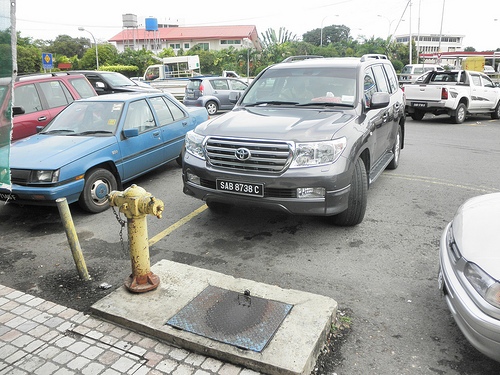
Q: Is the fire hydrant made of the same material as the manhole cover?
A: Yes, both the fire hydrant and the manhole cover are made of metal.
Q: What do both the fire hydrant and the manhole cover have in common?
A: The material, both the fire hydrant and the manhole cover are metallic.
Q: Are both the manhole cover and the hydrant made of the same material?
A: Yes, both the manhole cover and the hydrant are made of metal.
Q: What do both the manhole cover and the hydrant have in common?
A: The material, both the manhole cover and the hydrant are metallic.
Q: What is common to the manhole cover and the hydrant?
A: The material, both the manhole cover and the hydrant are metallic.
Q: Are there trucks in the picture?
A: Yes, there is a truck.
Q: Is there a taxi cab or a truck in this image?
A: Yes, there is a truck.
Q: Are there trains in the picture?
A: No, there are no trains.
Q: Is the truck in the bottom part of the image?
A: No, the truck is in the top of the image.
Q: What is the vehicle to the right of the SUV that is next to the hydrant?
A: The vehicle is a truck.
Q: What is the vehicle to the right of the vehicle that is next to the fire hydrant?
A: The vehicle is a truck.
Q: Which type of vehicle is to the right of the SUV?
A: The vehicle is a truck.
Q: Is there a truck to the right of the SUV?
A: Yes, there is a truck to the right of the SUV.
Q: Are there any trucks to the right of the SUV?
A: Yes, there is a truck to the right of the SUV.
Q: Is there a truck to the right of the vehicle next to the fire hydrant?
A: Yes, there is a truck to the right of the SUV.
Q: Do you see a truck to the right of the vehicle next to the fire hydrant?
A: Yes, there is a truck to the right of the SUV.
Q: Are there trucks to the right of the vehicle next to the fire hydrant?
A: Yes, there is a truck to the right of the SUV.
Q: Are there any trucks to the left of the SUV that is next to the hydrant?
A: No, the truck is to the right of the SUV.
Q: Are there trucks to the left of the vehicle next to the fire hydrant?
A: No, the truck is to the right of the SUV.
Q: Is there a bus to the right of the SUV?
A: No, there is a truck to the right of the SUV.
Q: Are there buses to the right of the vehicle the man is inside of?
A: No, there is a truck to the right of the SUV.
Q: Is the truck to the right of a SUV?
A: Yes, the truck is to the right of a SUV.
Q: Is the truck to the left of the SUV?
A: No, the truck is to the right of the SUV.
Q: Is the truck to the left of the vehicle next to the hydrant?
A: No, the truck is to the right of the SUV.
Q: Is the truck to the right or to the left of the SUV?
A: The truck is to the right of the SUV.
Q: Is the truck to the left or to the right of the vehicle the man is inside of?
A: The truck is to the right of the SUV.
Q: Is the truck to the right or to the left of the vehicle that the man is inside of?
A: The truck is to the right of the SUV.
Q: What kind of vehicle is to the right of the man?
A: The vehicle is a truck.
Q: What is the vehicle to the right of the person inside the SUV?
A: The vehicle is a truck.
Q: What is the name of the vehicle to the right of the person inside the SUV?
A: The vehicle is a truck.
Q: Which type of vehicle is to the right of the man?
A: The vehicle is a truck.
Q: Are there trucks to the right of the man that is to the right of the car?
A: Yes, there is a truck to the right of the man.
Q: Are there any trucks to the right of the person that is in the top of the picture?
A: Yes, there is a truck to the right of the man.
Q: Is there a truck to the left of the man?
A: No, the truck is to the right of the man.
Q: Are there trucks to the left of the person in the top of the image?
A: No, the truck is to the right of the man.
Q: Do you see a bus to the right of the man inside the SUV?
A: No, there is a truck to the right of the man.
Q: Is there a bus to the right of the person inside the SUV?
A: No, there is a truck to the right of the man.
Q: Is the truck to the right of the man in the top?
A: Yes, the truck is to the right of the man.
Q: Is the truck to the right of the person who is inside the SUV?
A: Yes, the truck is to the right of the man.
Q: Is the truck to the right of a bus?
A: No, the truck is to the right of the man.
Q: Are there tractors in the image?
A: No, there are no tractors.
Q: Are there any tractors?
A: No, there are no tractors.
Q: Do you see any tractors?
A: No, there are no tractors.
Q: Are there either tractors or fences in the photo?
A: No, there are no tractors or fences.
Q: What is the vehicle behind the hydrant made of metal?
A: The vehicle is a SUV.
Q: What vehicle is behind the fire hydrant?
A: The vehicle is a SUV.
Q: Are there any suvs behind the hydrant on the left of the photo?
A: Yes, there is a SUV behind the fire hydrant.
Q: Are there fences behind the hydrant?
A: No, there is a SUV behind the hydrant.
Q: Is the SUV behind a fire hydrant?
A: Yes, the SUV is behind a fire hydrant.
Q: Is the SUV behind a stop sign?
A: No, the SUV is behind a fire hydrant.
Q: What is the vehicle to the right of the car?
A: The vehicle is a SUV.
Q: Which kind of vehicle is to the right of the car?
A: The vehicle is a SUV.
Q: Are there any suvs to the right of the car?
A: Yes, there is a SUV to the right of the car.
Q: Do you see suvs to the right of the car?
A: Yes, there is a SUV to the right of the car.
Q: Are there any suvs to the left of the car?
A: No, the SUV is to the right of the car.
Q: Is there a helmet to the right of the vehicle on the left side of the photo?
A: No, there is a SUV to the right of the car.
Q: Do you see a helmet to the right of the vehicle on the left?
A: No, there is a SUV to the right of the car.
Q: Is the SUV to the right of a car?
A: Yes, the SUV is to the right of a car.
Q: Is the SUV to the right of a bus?
A: No, the SUV is to the right of a car.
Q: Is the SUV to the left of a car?
A: No, the SUV is to the right of a car.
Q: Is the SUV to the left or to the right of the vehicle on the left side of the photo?
A: The SUV is to the right of the car.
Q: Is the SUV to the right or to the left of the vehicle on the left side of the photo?
A: The SUV is to the right of the car.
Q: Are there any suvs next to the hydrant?
A: Yes, there is a SUV next to the hydrant.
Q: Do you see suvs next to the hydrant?
A: Yes, there is a SUV next to the hydrant.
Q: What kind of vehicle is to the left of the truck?
A: The vehicle is a SUV.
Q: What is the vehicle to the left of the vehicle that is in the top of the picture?
A: The vehicle is a SUV.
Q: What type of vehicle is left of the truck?
A: The vehicle is a SUV.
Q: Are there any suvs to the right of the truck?
A: No, the SUV is to the left of the truck.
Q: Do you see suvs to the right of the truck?
A: No, the SUV is to the left of the truck.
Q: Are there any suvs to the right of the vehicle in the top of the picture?
A: No, the SUV is to the left of the truck.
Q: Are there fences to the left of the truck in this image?
A: No, there is a SUV to the left of the truck.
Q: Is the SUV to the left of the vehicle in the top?
A: Yes, the SUV is to the left of the truck.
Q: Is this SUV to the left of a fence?
A: No, the SUV is to the left of the truck.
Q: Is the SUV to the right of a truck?
A: No, the SUV is to the left of a truck.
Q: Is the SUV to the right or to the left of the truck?
A: The SUV is to the left of the truck.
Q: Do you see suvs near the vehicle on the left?
A: Yes, there is a SUV near the car.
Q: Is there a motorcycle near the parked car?
A: No, there is a SUV near the car.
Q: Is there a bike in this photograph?
A: No, there are no bikes.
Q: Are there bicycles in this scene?
A: No, there are no bicycles.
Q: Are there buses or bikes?
A: No, there are no bikes or buses.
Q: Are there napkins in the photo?
A: No, there are no napkins.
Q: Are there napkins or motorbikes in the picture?
A: No, there are no napkins or motorbikes.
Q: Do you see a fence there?
A: No, there are no fences.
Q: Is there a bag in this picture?
A: No, there are no bags.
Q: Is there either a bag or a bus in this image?
A: No, there are no bags or buses.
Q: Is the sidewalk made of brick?
A: Yes, the sidewalk is made of brick.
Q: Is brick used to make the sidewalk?
A: Yes, the sidewalk is made of brick.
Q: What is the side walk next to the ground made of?
A: The sidewalk is made of brick.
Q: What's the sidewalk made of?
A: The sidewalk is made of brick.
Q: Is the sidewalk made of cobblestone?
A: No, the sidewalk is made of brick.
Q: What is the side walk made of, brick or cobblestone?
A: The side walk is made of brick.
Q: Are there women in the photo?
A: No, there are no women.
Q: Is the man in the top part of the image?
A: Yes, the man is in the top of the image.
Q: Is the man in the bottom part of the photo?
A: No, the man is in the top of the image.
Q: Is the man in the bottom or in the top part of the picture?
A: The man is in the top of the image.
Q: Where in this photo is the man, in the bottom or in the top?
A: The man is in the top of the image.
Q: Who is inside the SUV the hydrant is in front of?
A: The man is inside the SUV.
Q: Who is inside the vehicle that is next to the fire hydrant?
A: The man is inside the SUV.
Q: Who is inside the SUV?
A: The man is inside the SUV.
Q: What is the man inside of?
A: The man is inside the SUV.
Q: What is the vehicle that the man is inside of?
A: The vehicle is a SUV.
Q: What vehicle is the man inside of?
A: The man is inside the SUV.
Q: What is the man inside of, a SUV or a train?
A: The man is inside a SUV.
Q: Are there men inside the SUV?
A: Yes, there is a man inside the SUV.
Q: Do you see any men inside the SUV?
A: Yes, there is a man inside the SUV.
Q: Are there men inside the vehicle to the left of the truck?
A: Yes, there is a man inside the SUV.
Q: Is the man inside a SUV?
A: Yes, the man is inside a SUV.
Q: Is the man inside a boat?
A: No, the man is inside a SUV.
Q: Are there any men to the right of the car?
A: Yes, there is a man to the right of the car.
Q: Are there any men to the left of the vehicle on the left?
A: No, the man is to the right of the car.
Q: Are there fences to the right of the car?
A: No, there is a man to the right of the car.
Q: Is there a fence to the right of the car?
A: No, there is a man to the right of the car.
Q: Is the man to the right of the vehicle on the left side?
A: Yes, the man is to the right of the car.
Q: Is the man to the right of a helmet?
A: No, the man is to the right of the car.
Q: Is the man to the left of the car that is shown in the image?
A: No, the man is to the right of the car.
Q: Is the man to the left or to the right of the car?
A: The man is to the right of the car.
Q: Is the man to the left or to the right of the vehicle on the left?
A: The man is to the right of the car.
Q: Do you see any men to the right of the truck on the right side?
A: No, the man is to the left of the truck.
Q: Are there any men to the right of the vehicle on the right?
A: No, the man is to the left of the truck.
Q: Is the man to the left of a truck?
A: Yes, the man is to the left of a truck.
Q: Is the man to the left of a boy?
A: No, the man is to the left of a truck.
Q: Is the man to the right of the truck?
A: No, the man is to the left of the truck.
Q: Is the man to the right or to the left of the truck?
A: The man is to the left of the truck.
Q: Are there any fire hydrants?
A: Yes, there is a fire hydrant.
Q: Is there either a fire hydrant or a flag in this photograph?
A: Yes, there is a fire hydrant.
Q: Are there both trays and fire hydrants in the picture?
A: No, there is a fire hydrant but no trays.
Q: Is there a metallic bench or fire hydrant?
A: Yes, there is a metal fire hydrant.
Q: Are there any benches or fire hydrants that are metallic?
A: Yes, the fire hydrant is metallic.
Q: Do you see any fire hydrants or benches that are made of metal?
A: Yes, the fire hydrant is made of metal.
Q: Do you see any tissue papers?
A: No, there are no tissue papers.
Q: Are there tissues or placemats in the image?
A: No, there are no tissues or placemats.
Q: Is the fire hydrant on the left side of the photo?
A: Yes, the fire hydrant is on the left of the image.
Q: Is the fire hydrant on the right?
A: No, the fire hydrant is on the left of the image.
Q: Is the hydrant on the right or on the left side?
A: The hydrant is on the left of the image.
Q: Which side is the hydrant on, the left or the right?
A: The hydrant is on the left of the image.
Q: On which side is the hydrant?
A: The hydrant is on the left of the image.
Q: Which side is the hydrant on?
A: The hydrant is on the left of the image.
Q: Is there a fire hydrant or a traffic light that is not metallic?
A: No, there is a fire hydrant but it is metallic.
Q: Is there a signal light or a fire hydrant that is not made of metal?
A: No, there is a fire hydrant but it is made of metal.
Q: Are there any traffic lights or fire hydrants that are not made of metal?
A: No, there is a fire hydrant but it is made of metal.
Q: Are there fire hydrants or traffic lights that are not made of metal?
A: No, there is a fire hydrant but it is made of metal.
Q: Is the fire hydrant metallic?
A: Yes, the fire hydrant is metallic.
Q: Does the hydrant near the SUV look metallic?
A: Yes, the hydrant is metallic.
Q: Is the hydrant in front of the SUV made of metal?
A: Yes, the fire hydrant is made of metal.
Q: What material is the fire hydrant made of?
A: The fire hydrant is made of metal.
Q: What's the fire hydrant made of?
A: The fire hydrant is made of metal.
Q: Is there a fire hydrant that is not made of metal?
A: No, there is a fire hydrant but it is made of metal.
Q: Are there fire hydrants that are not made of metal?
A: No, there is a fire hydrant but it is made of metal.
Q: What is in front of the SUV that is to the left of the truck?
A: The fire hydrant is in front of the SUV.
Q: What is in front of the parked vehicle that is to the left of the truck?
A: The fire hydrant is in front of the SUV.